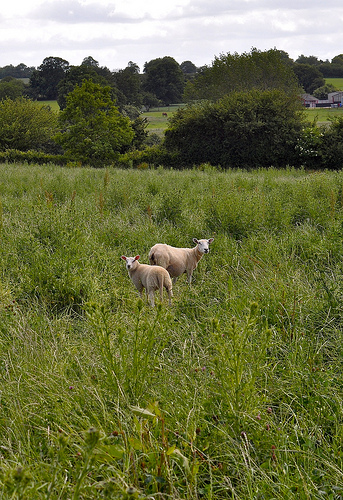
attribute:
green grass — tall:
[58, 377, 239, 480]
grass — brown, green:
[1, 101, 335, 496]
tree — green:
[314, 111, 342, 173]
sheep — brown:
[121, 255, 175, 304]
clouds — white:
[78, 6, 329, 85]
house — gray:
[295, 91, 342, 108]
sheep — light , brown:
[152, 240, 200, 271]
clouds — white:
[35, 2, 158, 47]